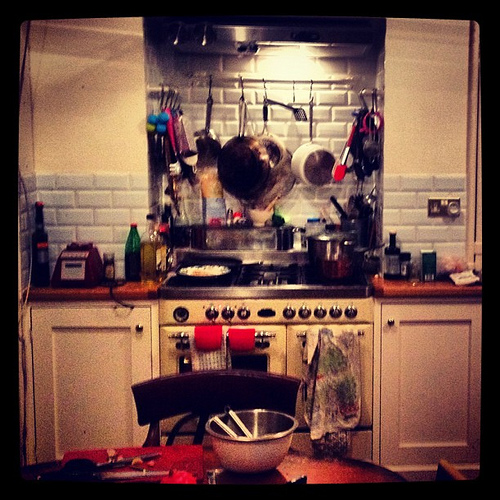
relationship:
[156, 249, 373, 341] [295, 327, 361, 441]
stove with door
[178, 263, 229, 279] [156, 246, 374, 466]
food cooking on stove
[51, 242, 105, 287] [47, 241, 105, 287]
appliance of appliance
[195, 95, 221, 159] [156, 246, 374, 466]
artifact hanging over stove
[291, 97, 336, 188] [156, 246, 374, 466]
artifact hanging over stove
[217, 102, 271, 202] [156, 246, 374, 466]
artifact hanging over stove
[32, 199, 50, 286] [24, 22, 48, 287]
bottle in corner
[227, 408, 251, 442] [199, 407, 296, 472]
spoon in bowl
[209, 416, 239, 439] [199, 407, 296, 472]
spoon in bowl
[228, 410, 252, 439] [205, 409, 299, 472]
spoon in bowl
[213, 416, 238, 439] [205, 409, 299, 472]
spoon in bowl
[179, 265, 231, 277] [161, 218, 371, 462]
food on top of stove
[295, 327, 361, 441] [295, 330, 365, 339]
door hanging from handle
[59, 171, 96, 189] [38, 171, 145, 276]
tile on wall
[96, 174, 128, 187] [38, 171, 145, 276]
tile on wall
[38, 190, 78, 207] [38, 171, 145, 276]
tile on wall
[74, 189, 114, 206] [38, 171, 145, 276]
tile on wall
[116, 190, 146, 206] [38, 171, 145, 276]
tile on wall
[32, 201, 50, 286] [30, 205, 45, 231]
bottle has neck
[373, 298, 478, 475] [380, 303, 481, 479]
closet has closet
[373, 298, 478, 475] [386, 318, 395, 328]
closet has handle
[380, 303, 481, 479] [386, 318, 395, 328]
closet has handle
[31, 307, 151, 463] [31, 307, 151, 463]
cabinet door has cabinet door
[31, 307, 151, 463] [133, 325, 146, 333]
cabinet door has handle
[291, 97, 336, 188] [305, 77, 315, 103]
artifact hanging on hook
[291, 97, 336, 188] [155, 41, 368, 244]
artifact hanging on wall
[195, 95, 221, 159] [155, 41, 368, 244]
artifact hanging on wall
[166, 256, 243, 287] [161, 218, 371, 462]
appliances on stove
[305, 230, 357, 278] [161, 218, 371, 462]
pot on stove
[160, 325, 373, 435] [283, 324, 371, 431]
stove's door hanging on door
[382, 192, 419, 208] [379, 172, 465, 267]
subway tile on wall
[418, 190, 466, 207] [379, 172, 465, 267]
subway tile on wall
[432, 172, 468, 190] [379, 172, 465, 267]
subway tile on wall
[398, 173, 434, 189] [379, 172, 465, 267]
subway tile on wall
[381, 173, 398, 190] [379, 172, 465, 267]
subway tile on wall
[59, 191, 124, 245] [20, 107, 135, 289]
tile on wall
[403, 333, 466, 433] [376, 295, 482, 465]
paint on door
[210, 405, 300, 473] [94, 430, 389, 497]
bowl on table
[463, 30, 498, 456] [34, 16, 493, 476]
frame on picture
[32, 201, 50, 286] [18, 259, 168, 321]
bottle on counter